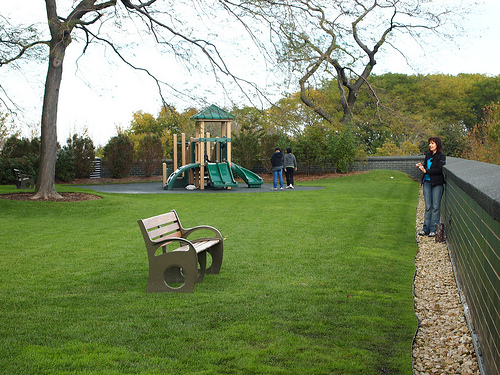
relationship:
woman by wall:
[416, 136, 448, 238] [350, 154, 495, 374]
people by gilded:
[269, 148, 300, 190] [161, 118, 234, 189]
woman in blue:
[416, 136, 448, 238] [423, 159, 440, 185]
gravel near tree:
[3, 190, 110, 204] [1, 1, 191, 204]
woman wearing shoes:
[416, 136, 448, 238] [418, 226, 443, 239]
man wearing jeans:
[270, 147, 286, 192] [270, 168, 287, 190]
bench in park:
[138, 208, 224, 298] [3, 4, 498, 371]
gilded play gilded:
[161, 118, 234, 189] [161, 118, 234, 189]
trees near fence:
[2, 106, 367, 192] [58, 152, 437, 191]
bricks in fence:
[480, 211, 499, 300] [58, 152, 437, 191]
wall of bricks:
[350, 154, 495, 374] [480, 211, 499, 300]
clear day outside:
[73, 59, 143, 143] [1, 0, 491, 374]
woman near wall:
[416, 136, 448, 238] [350, 154, 495, 374]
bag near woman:
[435, 221, 445, 243] [416, 136, 448, 238]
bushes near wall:
[5, 133, 168, 185] [350, 154, 495, 374]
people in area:
[269, 148, 300, 190] [238, 116, 345, 191]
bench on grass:
[138, 208, 224, 298] [2, 169, 415, 370]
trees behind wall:
[2, 106, 367, 192] [58, 152, 437, 191]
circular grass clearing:
[1, 185, 104, 208] [3, 190, 110, 204]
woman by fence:
[416, 136, 448, 238] [58, 152, 437, 191]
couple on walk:
[269, 148, 300, 190] [105, 180, 309, 199]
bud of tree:
[5, 182, 98, 207] [1, 1, 191, 204]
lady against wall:
[416, 136, 448, 238] [350, 154, 495, 374]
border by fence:
[412, 173, 475, 372] [58, 152, 437, 191]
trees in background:
[2, 106, 367, 192] [4, 1, 490, 148]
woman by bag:
[416, 136, 448, 238] [435, 221, 445, 243]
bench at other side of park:
[7, 162, 38, 188] [1, 144, 464, 366]